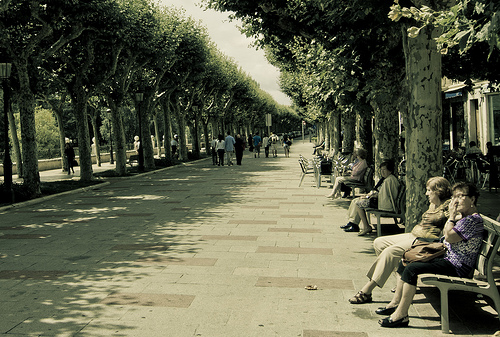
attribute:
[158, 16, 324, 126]
sky — hazy, gray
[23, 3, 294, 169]
trees — long, green